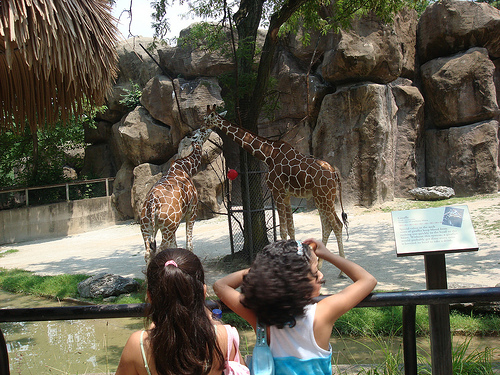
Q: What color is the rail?
A: The rail is black.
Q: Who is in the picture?
A: Two little girls are in the picture.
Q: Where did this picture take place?
A: It took place at the zoo.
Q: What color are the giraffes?
A: The giraffes are brown.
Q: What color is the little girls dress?
A: Her dress is blue and white.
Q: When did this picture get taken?
A: It was taken in the day time.